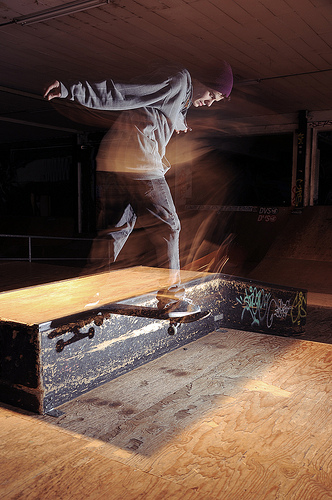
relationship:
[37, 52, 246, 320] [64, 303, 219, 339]
boy on skateboard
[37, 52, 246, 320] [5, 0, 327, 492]
boy doing trick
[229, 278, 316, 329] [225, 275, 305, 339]
graffiti on side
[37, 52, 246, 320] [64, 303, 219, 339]
boy standing on skateboard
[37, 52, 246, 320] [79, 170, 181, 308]
boy wearing pants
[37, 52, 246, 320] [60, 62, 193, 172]
boy wearing sweater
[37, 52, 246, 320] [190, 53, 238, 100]
boy wearing beanie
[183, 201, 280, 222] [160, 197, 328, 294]
stickers on ramp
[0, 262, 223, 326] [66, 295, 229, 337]
beam for support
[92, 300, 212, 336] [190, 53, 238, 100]
skateboard wearing beanie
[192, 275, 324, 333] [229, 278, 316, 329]
portion has graffiti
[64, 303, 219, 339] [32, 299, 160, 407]
skateboard hanging off end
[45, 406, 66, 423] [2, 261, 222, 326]
bracket connects ramp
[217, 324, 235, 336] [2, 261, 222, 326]
bracket connects ramp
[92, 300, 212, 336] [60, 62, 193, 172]
skateboard wearing sweater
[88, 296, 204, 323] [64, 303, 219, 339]
shoes on skateboard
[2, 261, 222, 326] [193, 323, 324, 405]
ramp casts shadow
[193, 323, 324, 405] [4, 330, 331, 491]
shadow on floor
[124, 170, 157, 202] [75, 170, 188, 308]
pocket on pants